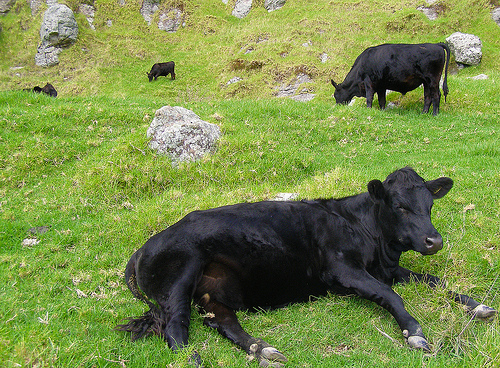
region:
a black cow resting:
[125, 164, 495, 367]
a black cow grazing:
[332, 36, 449, 106]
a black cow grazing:
[144, 60, 177, 84]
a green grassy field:
[4, 0, 499, 365]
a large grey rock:
[146, 103, 214, 160]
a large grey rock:
[35, 4, 78, 73]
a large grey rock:
[139, 1, 155, 26]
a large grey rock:
[156, 9, 186, 31]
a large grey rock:
[232, 0, 258, 17]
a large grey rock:
[448, 29, 480, 64]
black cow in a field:
[96, 167, 465, 325]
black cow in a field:
[320, 27, 473, 119]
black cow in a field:
[116, 51, 193, 97]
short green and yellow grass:
[9, 132, 64, 181]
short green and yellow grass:
[66, 141, 148, 207]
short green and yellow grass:
[16, 176, 101, 225]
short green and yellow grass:
[8, 217, 88, 282]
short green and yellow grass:
[28, 265, 93, 344]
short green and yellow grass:
[296, 313, 359, 365]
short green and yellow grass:
[433, 127, 477, 171]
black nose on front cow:
[421, 231, 448, 246]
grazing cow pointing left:
[325, 59, 358, 116]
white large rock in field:
[148, 105, 217, 156]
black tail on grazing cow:
[429, 33, 461, 117]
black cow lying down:
[118, 180, 473, 366]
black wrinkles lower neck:
[346, 203, 388, 258]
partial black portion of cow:
[26, 75, 63, 105]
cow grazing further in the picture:
[135, 39, 200, 97]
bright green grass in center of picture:
[253, 126, 335, 168]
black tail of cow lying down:
[126, 302, 173, 354]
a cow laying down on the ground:
[54, 61, 497, 356]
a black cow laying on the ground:
[79, 83, 498, 362]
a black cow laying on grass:
[48, 95, 498, 325]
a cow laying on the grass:
[83, 105, 498, 350]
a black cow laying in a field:
[49, 73, 489, 367]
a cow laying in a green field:
[122, 126, 497, 340]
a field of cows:
[22, 36, 499, 318]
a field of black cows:
[7, 23, 494, 345]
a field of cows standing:
[15, 20, 499, 296]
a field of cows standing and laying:
[32, 23, 499, 313]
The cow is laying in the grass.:
[147, 193, 423, 308]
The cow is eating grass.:
[306, 15, 467, 130]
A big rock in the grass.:
[126, 96, 228, 182]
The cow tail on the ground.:
[131, 289, 170, 339]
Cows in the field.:
[122, 35, 472, 129]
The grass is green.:
[42, 126, 147, 223]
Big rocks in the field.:
[26, 9, 188, 66]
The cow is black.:
[173, 181, 443, 312]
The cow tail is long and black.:
[440, 44, 453, 104]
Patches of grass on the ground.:
[231, 38, 322, 85]